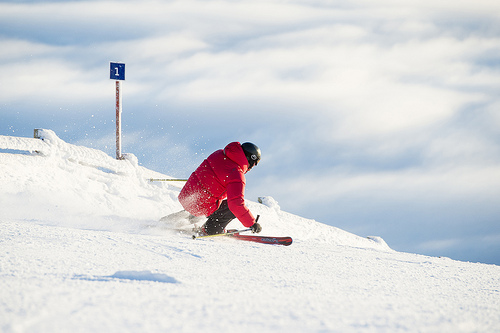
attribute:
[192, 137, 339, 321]
man — wearing, skiing, hunched over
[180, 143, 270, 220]
jacket — red, puffer, on, hooded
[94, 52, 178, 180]
post — behind, trail marker, Blue 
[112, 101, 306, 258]
person — skiing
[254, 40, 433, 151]
sky — cloudy, blue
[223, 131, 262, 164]
helmet — black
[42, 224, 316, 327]
snow — fresh, powder, mounds, white 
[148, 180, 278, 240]
pants — black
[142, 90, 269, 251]
coat — red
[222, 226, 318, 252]
ski — Red , black 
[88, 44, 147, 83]
1 — White 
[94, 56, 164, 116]
sign — blue 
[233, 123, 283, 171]
helmet — dark 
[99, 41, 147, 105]
square — blue 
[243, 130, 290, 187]
helmet — black 